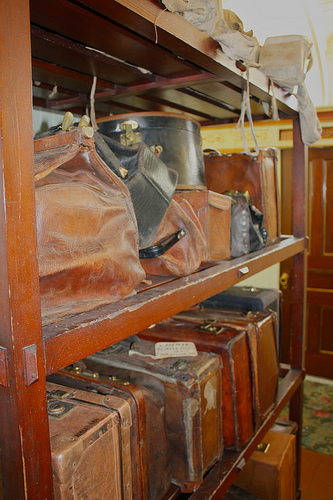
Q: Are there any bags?
A: Yes, there is a bag.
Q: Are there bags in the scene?
A: Yes, there is a bag.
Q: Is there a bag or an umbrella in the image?
A: Yes, there is a bag.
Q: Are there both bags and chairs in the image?
A: No, there is a bag but no chairs.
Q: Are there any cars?
A: No, there are no cars.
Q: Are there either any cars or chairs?
A: No, there are no cars or chairs.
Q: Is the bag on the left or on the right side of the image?
A: The bag is on the right of the image.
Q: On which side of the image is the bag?
A: The bag is on the right of the image.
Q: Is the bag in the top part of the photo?
A: Yes, the bag is in the top of the image.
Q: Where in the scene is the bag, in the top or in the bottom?
A: The bag is in the top of the image.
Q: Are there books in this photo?
A: No, there are no books.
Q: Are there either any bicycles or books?
A: No, there are no books or bicycles.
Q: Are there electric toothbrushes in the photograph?
A: No, there are no electric toothbrushes.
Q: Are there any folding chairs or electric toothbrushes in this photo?
A: No, there are no electric toothbrushes or folding chairs.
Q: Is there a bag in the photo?
A: Yes, there is a bag.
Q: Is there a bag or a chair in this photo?
A: Yes, there is a bag.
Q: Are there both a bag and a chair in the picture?
A: No, there is a bag but no chairs.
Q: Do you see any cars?
A: No, there are no cars.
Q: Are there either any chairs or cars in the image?
A: No, there are no cars or chairs.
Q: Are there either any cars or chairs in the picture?
A: No, there are no cars or chairs.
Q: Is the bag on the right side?
A: Yes, the bag is on the right of the image.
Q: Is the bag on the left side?
A: No, the bag is on the right of the image.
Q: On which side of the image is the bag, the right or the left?
A: The bag is on the right of the image.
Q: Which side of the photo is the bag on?
A: The bag is on the right of the image.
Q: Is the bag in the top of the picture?
A: Yes, the bag is in the top of the image.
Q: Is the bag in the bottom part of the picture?
A: No, the bag is in the top of the image.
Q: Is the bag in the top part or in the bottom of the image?
A: The bag is in the top of the image.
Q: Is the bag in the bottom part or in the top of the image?
A: The bag is in the top of the image.